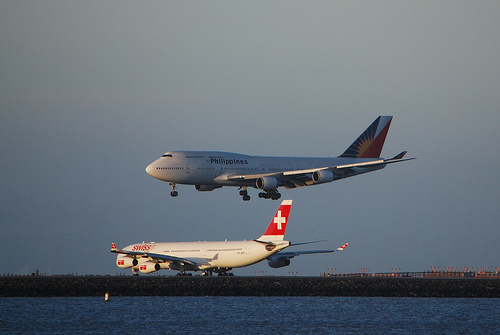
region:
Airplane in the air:
[134, 109, 428, 202]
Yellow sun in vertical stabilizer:
[346, 128, 380, 163]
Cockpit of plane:
[151, 143, 181, 171]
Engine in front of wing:
[254, 174, 279, 196]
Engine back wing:
[309, 167, 337, 187]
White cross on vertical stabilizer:
[254, 196, 298, 240]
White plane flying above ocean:
[99, 194, 355, 287]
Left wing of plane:
[96, 237, 205, 278]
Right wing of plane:
[279, 234, 353, 258]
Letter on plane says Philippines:
[201, 151, 251, 171]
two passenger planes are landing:
[83, 79, 434, 314]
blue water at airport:
[368, 308, 445, 327]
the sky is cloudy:
[89, 102, 168, 136]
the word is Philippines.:
[196, 149, 319, 215]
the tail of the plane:
[321, 81, 466, 211]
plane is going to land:
[153, 157, 370, 226]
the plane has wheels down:
[173, 172, 340, 251]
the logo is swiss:
[248, 192, 382, 292]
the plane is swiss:
[87, 217, 369, 297]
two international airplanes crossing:
[66, 92, 458, 296]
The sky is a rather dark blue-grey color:
[283, 19, 311, 99]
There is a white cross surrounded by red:
[267, 203, 298, 240]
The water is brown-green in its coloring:
[364, 301, 385, 332]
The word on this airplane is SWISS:
[131, 240, 153, 265]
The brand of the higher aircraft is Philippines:
[205, 154, 248, 171]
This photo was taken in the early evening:
[126, 75, 361, 333]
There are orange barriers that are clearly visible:
[427, 257, 451, 282]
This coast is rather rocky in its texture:
[43, 280, 55, 297]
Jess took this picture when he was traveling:
[124, 43, 370, 304]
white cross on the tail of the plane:
[269, 202, 292, 230]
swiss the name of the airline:
[131, 244, 153, 251]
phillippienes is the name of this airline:
[204, 154, 257, 169]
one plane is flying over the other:
[104, 98, 417, 285]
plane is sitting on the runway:
[107, 193, 358, 279]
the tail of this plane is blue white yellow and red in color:
[333, 108, 393, 161]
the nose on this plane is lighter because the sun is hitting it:
[136, 145, 186, 190]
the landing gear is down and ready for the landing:
[236, 187, 255, 206]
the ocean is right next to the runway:
[2, 295, 497, 332]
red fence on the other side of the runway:
[311, 265, 497, 281]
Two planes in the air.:
[101, 107, 458, 289]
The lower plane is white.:
[77, 192, 342, 292]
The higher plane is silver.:
[138, 112, 432, 203]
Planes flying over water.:
[0, 107, 497, 332]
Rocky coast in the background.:
[0, 252, 496, 305]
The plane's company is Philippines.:
[193, 150, 256, 168]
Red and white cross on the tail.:
[253, 192, 303, 237]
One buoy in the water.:
[95, 286, 117, 303]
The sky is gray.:
[0, 20, 497, 277]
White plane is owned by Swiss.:
[124, 240, 159, 254]